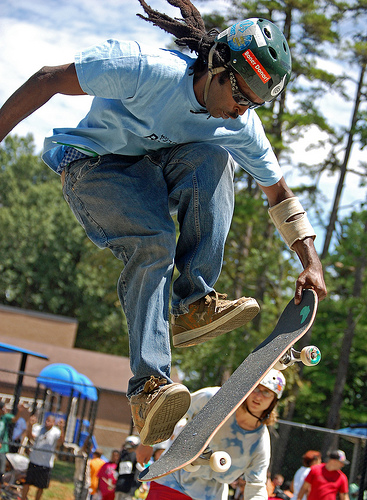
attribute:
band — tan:
[266, 203, 354, 261]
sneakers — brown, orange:
[120, 361, 201, 454]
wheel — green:
[301, 344, 323, 366]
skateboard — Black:
[133, 282, 321, 487]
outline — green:
[295, 302, 309, 324]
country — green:
[296, 303, 311, 325]